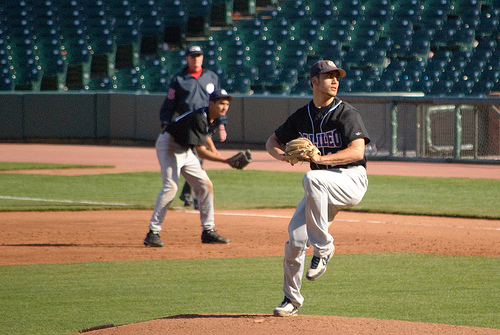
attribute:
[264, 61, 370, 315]
pitcher — pitching, baseball player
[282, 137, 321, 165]
cathcher's mitt — yellow, brown, baseball glove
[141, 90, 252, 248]
catcher — leaning forward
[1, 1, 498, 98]
bleachers — empty, green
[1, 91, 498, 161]
wall — gray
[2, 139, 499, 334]
field — part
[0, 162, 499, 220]
grass — neatly edged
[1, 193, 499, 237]
line — white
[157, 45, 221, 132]
base coach — standing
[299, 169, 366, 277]
leg — up in the air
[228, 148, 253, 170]
glove — black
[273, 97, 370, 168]
shirt — black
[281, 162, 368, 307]
pants — gray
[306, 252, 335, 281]
shoes — black, white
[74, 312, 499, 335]
mound — raised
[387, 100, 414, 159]
railings — green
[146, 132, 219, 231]
pants — white